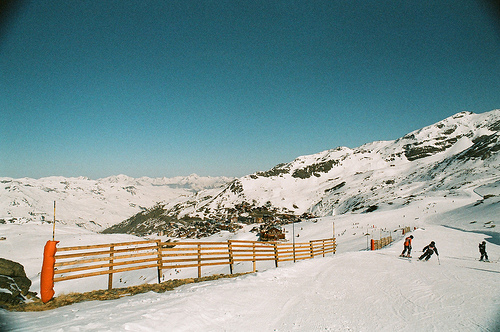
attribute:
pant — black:
[400, 244, 412, 255]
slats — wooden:
[33, 214, 381, 296]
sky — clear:
[9, 2, 485, 140]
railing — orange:
[68, 230, 307, 267]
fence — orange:
[28, 224, 349, 285]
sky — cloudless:
[186, 25, 293, 77]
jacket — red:
[400, 237, 413, 250]